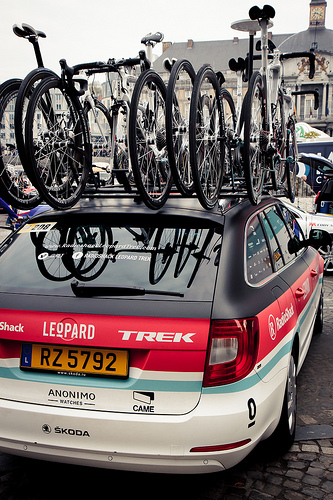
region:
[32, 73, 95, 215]
wheel of a bike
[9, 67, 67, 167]
wheel of a bike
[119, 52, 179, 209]
wheel of a bike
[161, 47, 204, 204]
wheel of a bike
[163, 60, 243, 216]
wheel of a bike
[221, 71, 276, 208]
wheel of a bike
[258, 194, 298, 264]
window of a car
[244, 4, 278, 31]
seat on a bike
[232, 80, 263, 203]
tire on a bike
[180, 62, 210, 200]
tire on a bike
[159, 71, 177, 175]
tire on a bike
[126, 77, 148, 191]
tire on a bike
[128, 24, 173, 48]
seat on a bike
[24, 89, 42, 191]
tire on a bike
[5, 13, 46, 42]
seat on a bike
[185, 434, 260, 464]
light on a car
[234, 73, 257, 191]
tire on a bike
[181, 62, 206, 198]
tire on a bike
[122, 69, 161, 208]
tire on a bike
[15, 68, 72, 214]
tire on a bike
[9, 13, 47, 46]
seat on a bike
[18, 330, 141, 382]
license plate on a car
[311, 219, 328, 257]
mirror on a car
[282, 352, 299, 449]
tire on a car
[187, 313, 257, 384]
light on a car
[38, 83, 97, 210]
wheel of a bike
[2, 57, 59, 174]
wheel of a bike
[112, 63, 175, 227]
wheel of a bike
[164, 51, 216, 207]
wheel of a bike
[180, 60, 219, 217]
wheel of a bike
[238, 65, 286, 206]
wheel of a bike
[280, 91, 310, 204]
wheel of a bike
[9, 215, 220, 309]
window of a car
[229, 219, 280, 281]
window of a car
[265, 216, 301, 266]
window of a car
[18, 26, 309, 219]
several bikes on top of car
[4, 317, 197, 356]
white letters on back of car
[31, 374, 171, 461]
black letters on back of car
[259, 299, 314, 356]
white letters on side of car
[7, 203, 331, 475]
a black red and white car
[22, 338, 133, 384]
a yellow and black license plate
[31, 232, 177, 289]
white letters on the back window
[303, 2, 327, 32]
a clock on a building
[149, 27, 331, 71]
a gray roof to building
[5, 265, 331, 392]
a blue stripe on car